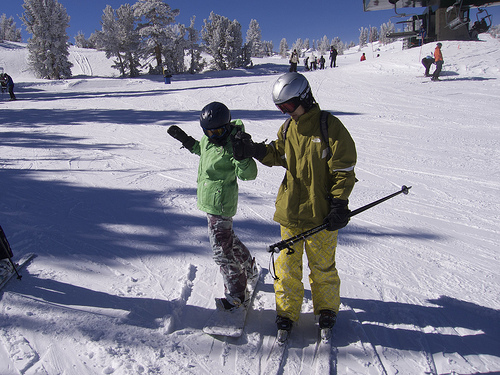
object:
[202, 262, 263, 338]
snowbaord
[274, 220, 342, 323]
pants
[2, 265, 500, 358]
people's shadow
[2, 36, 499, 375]
ground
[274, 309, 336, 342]
boots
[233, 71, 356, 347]
person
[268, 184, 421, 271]
poles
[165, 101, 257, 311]
boy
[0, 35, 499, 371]
snow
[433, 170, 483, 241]
ski tracks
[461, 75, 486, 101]
ski tracks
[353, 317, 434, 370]
ski tracks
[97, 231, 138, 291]
ski tracks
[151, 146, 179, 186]
ski tracks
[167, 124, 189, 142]
mitten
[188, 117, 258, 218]
green jacket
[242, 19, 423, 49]
trees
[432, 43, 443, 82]
person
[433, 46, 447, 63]
jacket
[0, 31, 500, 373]
slope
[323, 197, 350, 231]
glove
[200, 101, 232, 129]
helmet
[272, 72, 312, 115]
helmet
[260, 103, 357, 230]
coat